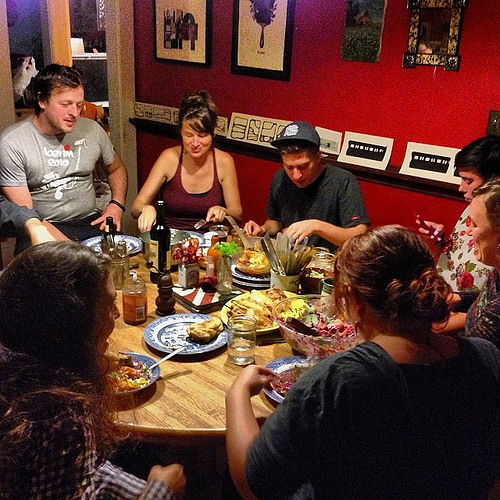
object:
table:
[102, 233, 367, 442]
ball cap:
[270, 121, 320, 149]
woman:
[130, 89, 243, 235]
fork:
[194, 217, 213, 229]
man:
[243, 118, 372, 258]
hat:
[267, 120, 322, 148]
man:
[0, 64, 128, 258]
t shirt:
[1, 114, 116, 223]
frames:
[151, 2, 213, 69]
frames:
[229, 1, 295, 83]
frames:
[341, 1, 388, 63]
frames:
[402, 0, 467, 71]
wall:
[133, 0, 500, 268]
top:
[162, 140, 223, 233]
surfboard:
[40, 138, 90, 200]